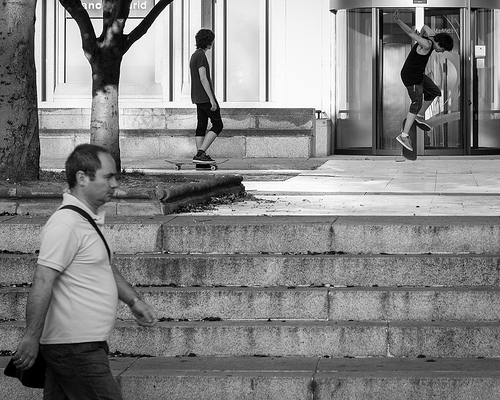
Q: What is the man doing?
A: The man is walking.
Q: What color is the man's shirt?
A: The man's shirt is white.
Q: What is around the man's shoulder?
A: A shoulder bag strap is around the man's shoulder.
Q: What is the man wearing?
A: The man is wearing a white shirt.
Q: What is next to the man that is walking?
A: There are steps next to the man.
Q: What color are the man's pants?
A: The man's pant's are grayish/black.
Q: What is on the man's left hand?
A: There is a watch on the man's left hand.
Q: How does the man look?
A: The man looks pensive.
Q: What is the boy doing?
A: The boy is jumping in front of the door.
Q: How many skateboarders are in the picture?
A: Two.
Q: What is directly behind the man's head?
A: A tree.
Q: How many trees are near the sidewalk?
A: Two.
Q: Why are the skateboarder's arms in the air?
A: He is trying a trick.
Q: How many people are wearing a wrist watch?
A: One.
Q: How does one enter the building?
A: Through the revolving door.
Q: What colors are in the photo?
A: Black and white.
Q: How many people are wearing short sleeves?
A: Two.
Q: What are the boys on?
A: Skateboards.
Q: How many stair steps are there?
A: Five.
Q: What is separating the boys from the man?
A: The stairs.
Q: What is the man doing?
A: Walking.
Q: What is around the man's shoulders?
A: A bag.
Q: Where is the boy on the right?
A: In the air.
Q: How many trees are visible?
A: Two.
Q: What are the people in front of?
A: A building.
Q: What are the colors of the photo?
A: Black and white.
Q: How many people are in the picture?
A: 3.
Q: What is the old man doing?
A: Walking.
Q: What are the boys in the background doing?
A: Skateboarding.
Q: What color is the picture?
A: Black and white.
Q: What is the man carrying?
A: A satchel.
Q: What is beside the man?
A: Stairs.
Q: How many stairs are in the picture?
A: 5.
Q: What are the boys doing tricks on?
A: Skateboards.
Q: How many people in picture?
A: 3.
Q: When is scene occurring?
A: Daytime.